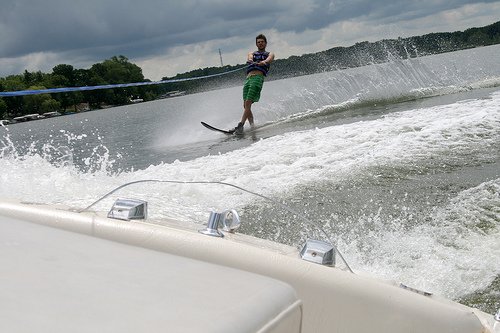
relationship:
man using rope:
[209, 18, 303, 140] [1, 47, 266, 115]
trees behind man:
[3, 0, 487, 108] [209, 18, 303, 140]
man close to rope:
[209, 18, 303, 140] [1, 47, 266, 115]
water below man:
[3, 65, 500, 295] [209, 18, 303, 140]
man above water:
[209, 18, 303, 140] [3, 65, 500, 295]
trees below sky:
[3, 0, 487, 108] [0, 6, 498, 63]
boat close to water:
[7, 200, 497, 332] [3, 65, 500, 295]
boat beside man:
[7, 200, 497, 332] [209, 18, 303, 140]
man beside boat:
[209, 18, 303, 140] [7, 200, 497, 332]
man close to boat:
[209, 18, 303, 140] [7, 200, 497, 332]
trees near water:
[6, 54, 144, 124] [4, 38, 496, 305]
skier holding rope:
[230, 32, 273, 134] [1, 47, 266, 115]